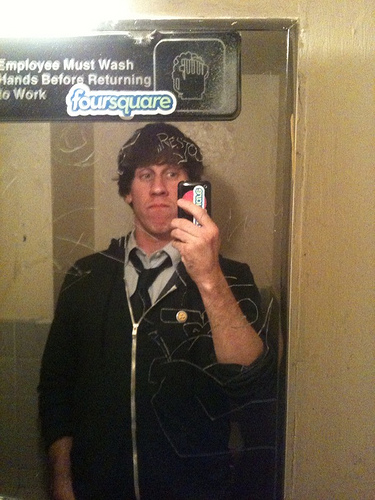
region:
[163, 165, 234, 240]
phone in man's hand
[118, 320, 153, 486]
zipper on a sweatshirt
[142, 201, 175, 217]
mouth on a man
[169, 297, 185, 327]
pin on a sweatshirt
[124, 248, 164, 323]
black tie on a man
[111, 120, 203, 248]
face of a man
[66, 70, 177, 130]
foursquare sign on the wall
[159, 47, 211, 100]
washing hands symbol on a sign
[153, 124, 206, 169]
writing on a mirror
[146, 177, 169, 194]
nose on a man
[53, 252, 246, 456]
the jacket is black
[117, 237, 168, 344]
the necktie is black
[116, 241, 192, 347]
the shirt is gray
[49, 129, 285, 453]
This is a man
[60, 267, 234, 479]
This is a mirror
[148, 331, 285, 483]
The mirror has scratches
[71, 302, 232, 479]
This is a jacket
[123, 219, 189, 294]
This is a tie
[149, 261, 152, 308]
The tie is black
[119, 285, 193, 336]
This is a button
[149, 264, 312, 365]
This is an arm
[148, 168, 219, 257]
This is a cell phone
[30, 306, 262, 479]
This is a bathroom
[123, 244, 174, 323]
one partially loosened dark tie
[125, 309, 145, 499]
one shiny metal zipper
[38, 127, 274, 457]
man taking picture in mirror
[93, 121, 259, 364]
man holding cell phone in left hand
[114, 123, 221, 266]
one man looking at cell phone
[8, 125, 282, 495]
man standing in bathroom with cell phone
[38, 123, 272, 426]
man wearing dark jacket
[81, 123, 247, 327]
man wearing gray collared shirt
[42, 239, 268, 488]
partially zippered dark jacket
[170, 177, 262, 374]
hand holding red and black cell phone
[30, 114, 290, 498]
person with brown hair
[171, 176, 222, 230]
cell phone with sticker on it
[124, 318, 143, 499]
zipper on a sweater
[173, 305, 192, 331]
metal button on a sweater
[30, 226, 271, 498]
black sweater on a person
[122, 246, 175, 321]
black tie being worn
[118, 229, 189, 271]
collar on a grey shirt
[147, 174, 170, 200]
nose on a person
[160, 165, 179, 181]
eye of a person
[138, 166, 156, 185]
eye of a person